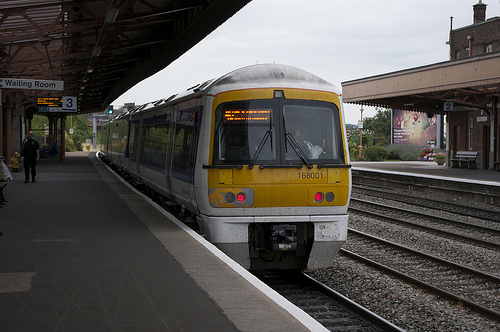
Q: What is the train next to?
A: Platform.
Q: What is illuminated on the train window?
A: Train route.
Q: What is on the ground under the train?
A: Tracks.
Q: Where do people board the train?
A: On platform.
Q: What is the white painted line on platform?
A: Safety line.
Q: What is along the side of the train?
A: Windows.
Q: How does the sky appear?
A: Cloudy.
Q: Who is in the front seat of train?
A: Conductor.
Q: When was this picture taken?
A: Daytime.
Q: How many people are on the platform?
A: One.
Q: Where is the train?
A: At a stop.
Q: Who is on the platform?
A: A man.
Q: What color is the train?
A: Yellow.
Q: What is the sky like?
A: Cloudy.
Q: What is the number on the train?
A: 168001.